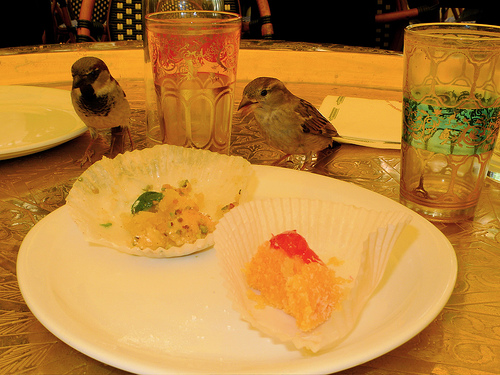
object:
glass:
[143, 10, 241, 155]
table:
[0, 41, 500, 374]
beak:
[234, 98, 257, 112]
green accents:
[402, 87, 498, 154]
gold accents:
[399, 22, 496, 209]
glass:
[179, 50, 204, 101]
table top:
[0, 51, 500, 374]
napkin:
[316, 95, 402, 149]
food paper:
[63, 142, 258, 258]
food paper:
[212, 196, 413, 354]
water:
[153, 71, 235, 153]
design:
[146, 26, 240, 78]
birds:
[237, 76, 342, 171]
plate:
[14, 161, 456, 374]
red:
[273, 232, 305, 251]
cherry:
[269, 230, 319, 261]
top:
[266, 231, 302, 258]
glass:
[399, 22, 500, 223]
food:
[247, 229, 345, 332]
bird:
[69, 55, 133, 167]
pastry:
[120, 178, 215, 250]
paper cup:
[65, 144, 257, 258]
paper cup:
[210, 197, 413, 352]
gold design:
[0, 178, 54, 273]